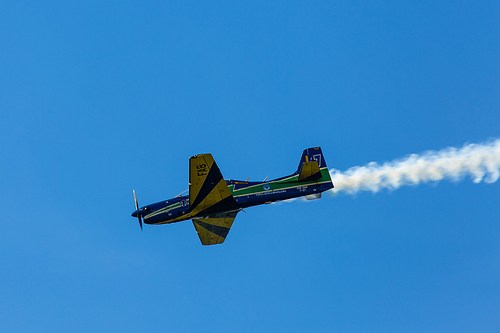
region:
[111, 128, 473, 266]
yellow and blue airplane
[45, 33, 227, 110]
pure blue clear sky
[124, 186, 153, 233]
airplane propeller spinning quickly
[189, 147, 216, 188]
black airline call letters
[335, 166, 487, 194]
trail of airplane smoke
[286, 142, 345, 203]
tail fin of an airplane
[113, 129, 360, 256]
airplane with a green stripe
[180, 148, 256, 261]
yellow and blue wings of an airplane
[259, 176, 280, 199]
blue circle on a green background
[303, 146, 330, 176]
number 7 on a blue background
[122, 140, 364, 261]
airplane flying in the sky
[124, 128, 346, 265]
blue and yellow airplane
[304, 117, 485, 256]
exhaust fumes in back of airplane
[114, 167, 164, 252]
airplane rotor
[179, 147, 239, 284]
two airplane wings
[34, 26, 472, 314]
colorful airplane flying on a clear day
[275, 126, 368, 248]
tail of airplane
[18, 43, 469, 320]
yellow, blue, and green plane flying with white exhaust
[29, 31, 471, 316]
clear day with no clouds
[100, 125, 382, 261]
plane painted yellow, blue and green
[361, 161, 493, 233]
Smoke coming out of plane.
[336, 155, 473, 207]
Smoke coming out of plane is white.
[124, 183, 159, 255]
Propeller on front of plane.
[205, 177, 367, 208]
Green strip on back of plane.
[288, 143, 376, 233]
Tail of plane is mostly blue.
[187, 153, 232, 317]
Wings are blue and yellow.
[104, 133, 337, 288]
Plane flying in the sky.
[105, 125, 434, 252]
Multi colored plane flying in the sky.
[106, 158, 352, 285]
Plane is in the air.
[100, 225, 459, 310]
Sky is clear and blue.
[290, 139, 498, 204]
Smoke pouring out of the back end of an airplane.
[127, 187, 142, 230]
Propeller on the front of an airplane.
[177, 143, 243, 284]
Large wingspan on a small plane.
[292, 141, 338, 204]
Tale wing on the back of a small airplane.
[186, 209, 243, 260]
Right wing on a small airplane.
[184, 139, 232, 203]
left wing on a small airplane.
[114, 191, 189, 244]
Front end of an airplane with propeller.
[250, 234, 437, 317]
Section of blue sky under airplane.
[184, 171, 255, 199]
Cockpit of a small airplane.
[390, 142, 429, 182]
White smoke in a clear blue sky.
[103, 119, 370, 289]
A plane is in mid air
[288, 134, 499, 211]
Plane is leaving behind a smoke trail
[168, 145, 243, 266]
Blue stripes are under the plane's wings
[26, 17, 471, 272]
The sky is blue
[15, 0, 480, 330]
The sky is clear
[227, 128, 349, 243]
The plane has a green stripe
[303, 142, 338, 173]
The plane's tail has the number 7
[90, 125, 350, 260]
The plane is dark blue in color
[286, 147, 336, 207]
Yellow is under the plane tail fins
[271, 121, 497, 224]
The plane's smoke is white in color